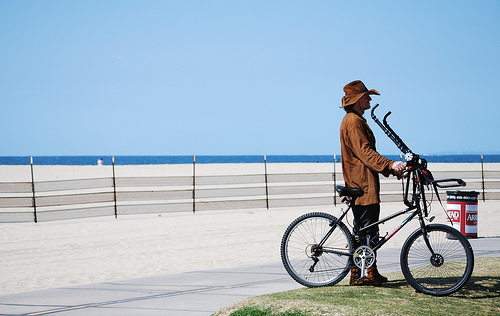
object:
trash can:
[443, 190, 482, 241]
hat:
[332, 76, 383, 108]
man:
[333, 78, 397, 287]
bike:
[278, 162, 478, 302]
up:
[221, 154, 478, 316]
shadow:
[381, 270, 500, 294]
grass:
[205, 258, 500, 316]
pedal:
[353, 271, 368, 287]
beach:
[0, 147, 338, 200]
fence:
[0, 157, 500, 224]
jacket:
[333, 111, 393, 208]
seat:
[333, 182, 366, 201]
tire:
[394, 223, 477, 299]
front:
[375, 199, 479, 302]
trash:
[442, 186, 481, 200]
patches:
[211, 292, 369, 316]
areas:
[216, 258, 499, 316]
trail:
[0, 237, 500, 315]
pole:
[186, 154, 207, 214]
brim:
[337, 86, 383, 108]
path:
[193, 227, 500, 279]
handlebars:
[389, 155, 438, 207]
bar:
[401, 185, 424, 207]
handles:
[396, 161, 441, 186]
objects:
[369, 100, 468, 208]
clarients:
[372, 102, 419, 158]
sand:
[91, 230, 169, 262]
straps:
[430, 177, 461, 226]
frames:
[394, 150, 465, 216]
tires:
[277, 211, 356, 288]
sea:
[0, 154, 500, 166]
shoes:
[348, 266, 381, 286]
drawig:
[442, 199, 480, 237]